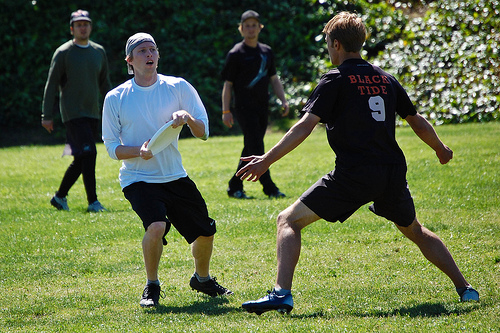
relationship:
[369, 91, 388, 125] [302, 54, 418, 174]
number on shirt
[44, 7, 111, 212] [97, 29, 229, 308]
man walking behind frisbee holder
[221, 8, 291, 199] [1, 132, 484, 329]
person in grass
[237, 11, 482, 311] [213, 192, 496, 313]
person in grass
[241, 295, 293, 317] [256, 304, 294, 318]
shoe has cleats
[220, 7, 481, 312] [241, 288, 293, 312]
man has foot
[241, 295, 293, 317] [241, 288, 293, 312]
shoe on foot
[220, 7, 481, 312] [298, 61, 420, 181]
man wearing shirt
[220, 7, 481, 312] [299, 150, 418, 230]
man wearing pants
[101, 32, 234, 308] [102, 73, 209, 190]
man wearing white shirt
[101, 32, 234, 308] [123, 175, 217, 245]
man wearing black shorts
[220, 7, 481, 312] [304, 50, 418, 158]
man wearing shirt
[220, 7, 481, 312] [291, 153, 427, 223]
man wearing shorts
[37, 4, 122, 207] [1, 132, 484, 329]
person on grass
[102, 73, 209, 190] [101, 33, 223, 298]
white shirt on man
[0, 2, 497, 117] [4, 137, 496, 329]
plant on field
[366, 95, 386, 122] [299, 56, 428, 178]
9 on back of shirt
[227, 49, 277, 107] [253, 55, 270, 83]
tshirt with blue design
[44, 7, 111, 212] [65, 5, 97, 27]
man wearing cap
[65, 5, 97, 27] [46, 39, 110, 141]
cap and shirt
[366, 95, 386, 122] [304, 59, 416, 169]
9 on shirt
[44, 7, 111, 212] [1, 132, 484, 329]
man walking in grass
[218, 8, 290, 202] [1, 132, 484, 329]
man walking in grass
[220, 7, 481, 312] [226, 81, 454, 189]
man standing with arms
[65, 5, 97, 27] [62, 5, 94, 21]
cap on mans head